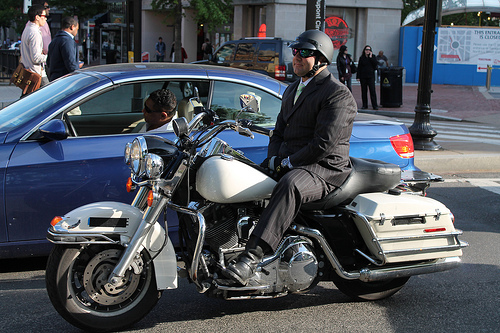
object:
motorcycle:
[45, 87, 468, 332]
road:
[1, 113, 500, 333]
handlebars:
[187, 106, 274, 145]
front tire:
[44, 238, 165, 332]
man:
[222, 29, 357, 285]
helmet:
[288, 30, 334, 79]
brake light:
[389, 132, 413, 158]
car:
[0, 62, 422, 260]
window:
[26, 79, 212, 143]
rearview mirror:
[51, 94, 66, 105]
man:
[138, 88, 179, 133]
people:
[9, 1, 84, 99]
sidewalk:
[415, 140, 500, 177]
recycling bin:
[379, 66, 404, 108]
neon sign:
[325, 16, 349, 48]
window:
[323, 5, 357, 65]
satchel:
[9, 63, 42, 94]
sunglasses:
[292, 48, 318, 58]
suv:
[189, 36, 300, 85]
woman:
[356, 45, 379, 110]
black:
[356, 54, 378, 108]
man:
[14, 4, 49, 97]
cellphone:
[367, 53, 370, 58]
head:
[142, 89, 177, 125]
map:
[436, 28, 500, 66]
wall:
[397, 25, 500, 87]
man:
[377, 51, 388, 83]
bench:
[375, 67, 381, 77]